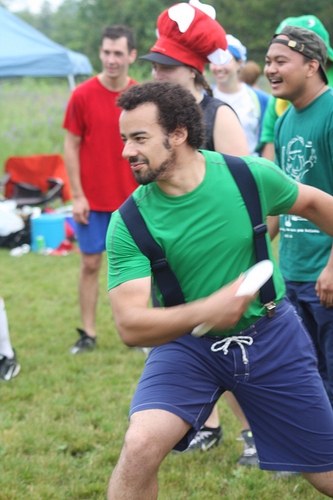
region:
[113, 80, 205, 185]
Man with curly brown hair and beard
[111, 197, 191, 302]
Navy blue suspender on green shirt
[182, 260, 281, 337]
Man holding a white frisbee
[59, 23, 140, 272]
Man in red shirt and blue shorts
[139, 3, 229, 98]
Woman wearing large red hat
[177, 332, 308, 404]
White tie string on blue shorts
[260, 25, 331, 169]
Man in green shirt and cap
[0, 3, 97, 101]
Blue tent behind people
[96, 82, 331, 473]
Man in green shirt and blue shorts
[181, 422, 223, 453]
Black and white sneaker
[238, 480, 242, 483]
part of a field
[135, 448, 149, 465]
part of a knee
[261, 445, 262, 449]
part of a short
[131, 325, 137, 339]
part of an elbow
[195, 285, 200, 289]
part of a shirt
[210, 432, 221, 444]
part of a boot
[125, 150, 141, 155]
nose of a man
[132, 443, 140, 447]
edge of a knee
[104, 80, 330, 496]
A man in a green shirt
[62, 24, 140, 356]
A man in a red shirt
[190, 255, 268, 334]
A white frisbee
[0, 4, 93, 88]
A blue canopy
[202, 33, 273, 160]
A person in a white shirt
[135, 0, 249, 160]
A person in a red and white hat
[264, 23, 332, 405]
A person in a dark green shirt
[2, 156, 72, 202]
An orange chair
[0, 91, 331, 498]
A large grassy field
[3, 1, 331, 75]
A forested area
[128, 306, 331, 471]
a pair of blue shorts with white stitching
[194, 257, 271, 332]
a white Frisbee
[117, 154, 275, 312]
a pair of wide black suspenders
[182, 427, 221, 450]
a white Nike symbol on black shoe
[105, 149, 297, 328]
a green short sleeve shirt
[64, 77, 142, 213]
a red short sleeve shirt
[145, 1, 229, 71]
a large red, white, and black unique hat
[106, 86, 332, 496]
a man throwing a Frisbee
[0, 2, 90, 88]
a green pop up tent for shade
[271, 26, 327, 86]
a dark hat with brass buckle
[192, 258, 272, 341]
the frisbee in the man's hand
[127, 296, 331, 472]
the blue shorts on the man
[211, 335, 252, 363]
the white string on the man's pants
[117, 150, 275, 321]
the man's suspenders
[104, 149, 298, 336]
the short sleeved green shirt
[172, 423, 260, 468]
the pair of shoes on the grass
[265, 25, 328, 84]
the hat on the man's head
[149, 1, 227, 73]
the large red hat in the back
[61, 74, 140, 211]
the short sleeved red shirt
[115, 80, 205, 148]
the curly hair on the man's head